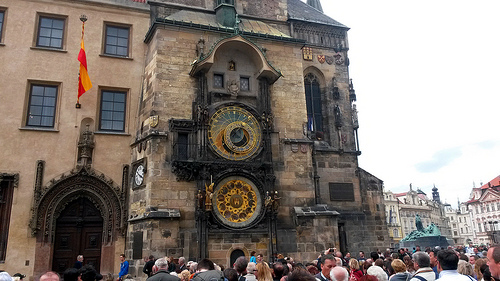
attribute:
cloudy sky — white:
[299, 0, 498, 207]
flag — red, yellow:
[78, 21, 93, 101]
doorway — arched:
[21, 150, 136, 273]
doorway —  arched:
[28, 111, 123, 279]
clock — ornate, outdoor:
[193, 91, 268, 266]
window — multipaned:
[38, 10, 68, 52]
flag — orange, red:
[73, 12, 96, 113]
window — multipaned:
[98, 83, 126, 136]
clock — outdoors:
[131, 157, 148, 190]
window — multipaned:
[22, 76, 59, 131]